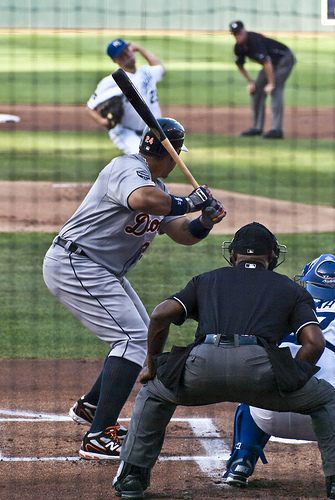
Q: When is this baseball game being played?
A: Daytime.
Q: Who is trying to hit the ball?
A: Number 24.